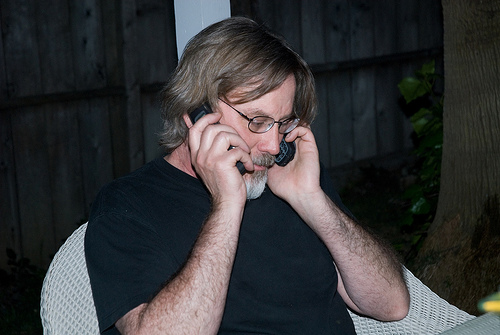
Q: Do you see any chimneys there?
A: No, there are no chimneys.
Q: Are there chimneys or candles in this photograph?
A: No, there are no chimneys or candles.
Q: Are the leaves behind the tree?
A: Yes, the leaves are behind the tree.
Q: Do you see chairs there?
A: Yes, there is a chair.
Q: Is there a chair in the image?
A: Yes, there is a chair.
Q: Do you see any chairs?
A: Yes, there is a chair.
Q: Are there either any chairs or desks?
A: Yes, there is a chair.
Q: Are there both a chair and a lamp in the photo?
A: No, there is a chair but no lamps.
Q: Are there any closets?
A: No, there are no closets.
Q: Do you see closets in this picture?
A: No, there are no closets.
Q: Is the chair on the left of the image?
A: Yes, the chair is on the left of the image.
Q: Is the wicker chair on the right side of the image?
A: No, the chair is on the left of the image.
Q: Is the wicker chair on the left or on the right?
A: The chair is on the left of the image.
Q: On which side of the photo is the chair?
A: The chair is on the left of the image.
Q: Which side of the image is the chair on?
A: The chair is on the left of the image.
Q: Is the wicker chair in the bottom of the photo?
A: Yes, the chair is in the bottom of the image.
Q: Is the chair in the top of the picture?
A: No, the chair is in the bottom of the image.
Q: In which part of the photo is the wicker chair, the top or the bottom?
A: The chair is in the bottom of the image.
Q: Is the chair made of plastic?
A: No, the chair is made of wicker.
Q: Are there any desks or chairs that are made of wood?
A: No, there is a chair but it is made of wicker.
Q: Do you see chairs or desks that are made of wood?
A: No, there is a chair but it is made of wicker.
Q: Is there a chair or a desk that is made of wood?
A: No, there is a chair but it is made of wicker.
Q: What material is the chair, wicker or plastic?
A: The chair is made of wicker.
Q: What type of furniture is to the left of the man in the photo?
A: The piece of furniture is a chair.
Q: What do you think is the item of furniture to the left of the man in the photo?
A: The piece of furniture is a chair.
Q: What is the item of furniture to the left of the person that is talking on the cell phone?
A: The piece of furniture is a chair.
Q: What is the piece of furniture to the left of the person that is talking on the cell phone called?
A: The piece of furniture is a chair.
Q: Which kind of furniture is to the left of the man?
A: The piece of furniture is a chair.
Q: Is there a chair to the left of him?
A: Yes, there is a chair to the left of the man.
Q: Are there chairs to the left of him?
A: Yes, there is a chair to the left of the man.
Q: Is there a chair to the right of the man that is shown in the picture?
A: No, the chair is to the left of the man.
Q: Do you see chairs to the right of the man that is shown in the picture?
A: No, the chair is to the left of the man.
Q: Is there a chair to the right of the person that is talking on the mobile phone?
A: No, the chair is to the left of the man.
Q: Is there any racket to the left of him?
A: No, there is a chair to the left of the man.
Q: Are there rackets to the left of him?
A: No, there is a chair to the left of the man.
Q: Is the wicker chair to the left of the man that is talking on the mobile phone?
A: Yes, the chair is to the left of the man.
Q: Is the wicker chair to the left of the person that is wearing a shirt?
A: Yes, the chair is to the left of the man.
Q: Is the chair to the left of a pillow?
A: No, the chair is to the left of the man.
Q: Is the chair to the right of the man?
A: No, the chair is to the left of the man.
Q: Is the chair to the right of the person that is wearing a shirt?
A: No, the chair is to the left of the man.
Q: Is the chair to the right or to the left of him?
A: The chair is to the left of the man.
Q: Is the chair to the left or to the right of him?
A: The chair is to the left of the man.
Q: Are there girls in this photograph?
A: No, there are no girls.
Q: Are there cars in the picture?
A: No, there are no cars.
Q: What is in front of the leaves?
A: The tree is in front of the leaves.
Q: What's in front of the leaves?
A: The tree is in front of the leaves.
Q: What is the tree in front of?
A: The tree is in front of the leaves.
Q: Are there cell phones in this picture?
A: Yes, there is a cell phone.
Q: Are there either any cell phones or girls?
A: Yes, there is a cell phone.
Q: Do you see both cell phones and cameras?
A: No, there is a cell phone but no cameras.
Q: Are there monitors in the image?
A: No, there are no monitors.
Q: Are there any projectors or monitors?
A: No, there are no monitors or projectors.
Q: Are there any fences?
A: Yes, there is a fence.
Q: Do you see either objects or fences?
A: Yes, there is a fence.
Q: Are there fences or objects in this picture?
A: Yes, there is a fence.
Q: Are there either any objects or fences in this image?
A: Yes, there is a fence.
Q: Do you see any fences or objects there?
A: Yes, there is a fence.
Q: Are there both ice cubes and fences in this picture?
A: No, there is a fence but no ice cubes.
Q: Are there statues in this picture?
A: No, there are no statues.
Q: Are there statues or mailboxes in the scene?
A: No, there are no statues or mailboxes.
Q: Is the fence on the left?
A: Yes, the fence is on the left of the image.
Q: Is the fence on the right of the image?
A: No, the fence is on the left of the image.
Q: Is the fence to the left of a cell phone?
A: Yes, the fence is to the left of a cell phone.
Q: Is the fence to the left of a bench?
A: No, the fence is to the left of a cell phone.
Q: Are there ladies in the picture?
A: No, there are no ladies.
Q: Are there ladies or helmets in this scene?
A: No, there are no ladies or helmets.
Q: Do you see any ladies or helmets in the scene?
A: No, there are no ladies or helmets.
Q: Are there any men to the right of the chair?
A: Yes, there is a man to the right of the chair.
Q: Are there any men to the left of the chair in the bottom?
A: No, the man is to the right of the chair.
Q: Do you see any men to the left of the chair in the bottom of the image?
A: No, the man is to the right of the chair.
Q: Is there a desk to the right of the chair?
A: No, there is a man to the right of the chair.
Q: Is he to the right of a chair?
A: Yes, the man is to the right of a chair.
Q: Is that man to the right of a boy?
A: No, the man is to the right of a chair.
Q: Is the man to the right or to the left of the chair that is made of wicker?
A: The man is to the right of the chair.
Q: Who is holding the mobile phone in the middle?
A: The man is holding the cell phone.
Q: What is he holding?
A: The man is holding the mobile phone.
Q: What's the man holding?
A: The man is holding the mobile phone.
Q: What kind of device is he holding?
A: The man is holding the cell phone.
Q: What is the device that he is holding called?
A: The device is a cell phone.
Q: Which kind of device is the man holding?
A: The man is holding the cell phone.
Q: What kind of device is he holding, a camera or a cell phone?
A: The man is holding a cell phone.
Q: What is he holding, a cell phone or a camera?
A: The man is holding a cell phone.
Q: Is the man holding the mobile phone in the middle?
A: Yes, the man is holding the mobile phone.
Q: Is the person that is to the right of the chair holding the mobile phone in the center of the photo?
A: Yes, the man is holding the mobile phone.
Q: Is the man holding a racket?
A: No, the man is holding the mobile phone.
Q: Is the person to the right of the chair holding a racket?
A: No, the man is holding the mobile phone.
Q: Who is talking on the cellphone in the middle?
A: The man is talking on the cellphone.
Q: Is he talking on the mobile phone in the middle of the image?
A: Yes, the man is talking on the cellphone.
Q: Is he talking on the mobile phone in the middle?
A: Yes, the man is talking on the cellphone.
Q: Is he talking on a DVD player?
A: No, the man is talking on the cellphone.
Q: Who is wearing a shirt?
A: The man is wearing a shirt.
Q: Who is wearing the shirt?
A: The man is wearing a shirt.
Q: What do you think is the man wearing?
A: The man is wearing a shirt.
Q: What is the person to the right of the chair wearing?
A: The man is wearing a shirt.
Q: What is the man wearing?
A: The man is wearing a shirt.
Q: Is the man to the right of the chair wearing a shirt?
A: Yes, the man is wearing a shirt.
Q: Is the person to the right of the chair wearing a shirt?
A: Yes, the man is wearing a shirt.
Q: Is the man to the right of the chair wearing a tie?
A: No, the man is wearing a shirt.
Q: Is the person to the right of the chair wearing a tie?
A: No, the man is wearing a shirt.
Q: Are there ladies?
A: No, there are no ladies.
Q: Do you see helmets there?
A: No, there are no helmets.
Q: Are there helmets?
A: No, there are no helmets.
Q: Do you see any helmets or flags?
A: No, there are no helmets or flags.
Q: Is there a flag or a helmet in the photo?
A: No, there are no helmets or flags.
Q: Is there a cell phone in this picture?
A: Yes, there is a cell phone.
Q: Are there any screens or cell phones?
A: Yes, there is a cell phone.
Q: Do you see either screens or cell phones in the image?
A: Yes, there is a cell phone.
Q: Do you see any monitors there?
A: No, there are no monitors.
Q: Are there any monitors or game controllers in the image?
A: No, there are no monitors or game controllers.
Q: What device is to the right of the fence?
A: The device is a cell phone.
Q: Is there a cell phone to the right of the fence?
A: Yes, there is a cell phone to the right of the fence.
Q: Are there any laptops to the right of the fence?
A: No, there is a cell phone to the right of the fence.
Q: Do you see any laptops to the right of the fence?
A: No, there is a cell phone to the right of the fence.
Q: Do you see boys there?
A: No, there are no boys.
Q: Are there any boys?
A: No, there are no boys.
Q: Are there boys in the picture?
A: No, there are no boys.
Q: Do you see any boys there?
A: No, there are no boys.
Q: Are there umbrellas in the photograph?
A: No, there are no umbrellas.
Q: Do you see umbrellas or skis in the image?
A: No, there are no umbrellas or skis.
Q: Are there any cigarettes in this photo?
A: No, there are no cigarettes.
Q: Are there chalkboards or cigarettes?
A: No, there are no cigarettes or chalkboards.